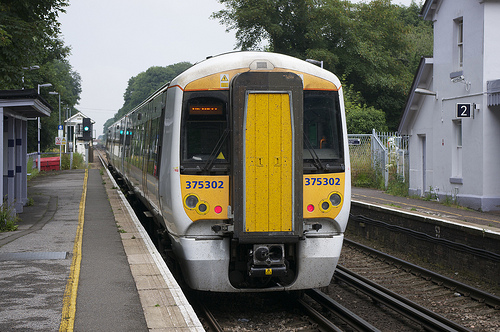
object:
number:
[192, 181, 198, 189]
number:
[205, 180, 211, 188]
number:
[305, 177, 311, 185]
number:
[328, 178, 334, 186]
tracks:
[300, 291, 379, 332]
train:
[101, 49, 356, 293]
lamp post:
[37, 82, 52, 172]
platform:
[0, 147, 206, 332]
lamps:
[214, 204, 223, 214]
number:
[212, 181, 218, 189]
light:
[84, 126, 89, 132]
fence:
[349, 130, 413, 189]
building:
[395, 0, 499, 214]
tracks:
[201, 297, 339, 332]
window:
[448, 118, 465, 184]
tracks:
[334, 238, 499, 332]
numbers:
[311, 178, 317, 186]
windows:
[300, 86, 344, 174]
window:
[451, 15, 468, 70]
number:
[218, 181, 224, 189]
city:
[0, 0, 500, 332]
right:
[365, 0, 500, 332]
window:
[180, 88, 235, 178]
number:
[186, 181, 192, 190]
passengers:
[136, 128, 145, 170]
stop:
[165, 51, 363, 306]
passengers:
[146, 121, 159, 175]